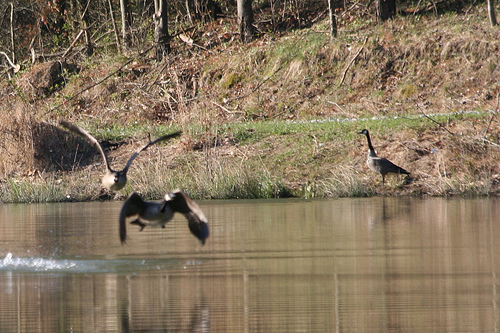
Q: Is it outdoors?
A: Yes, it is outdoors.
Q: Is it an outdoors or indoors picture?
A: It is outdoors.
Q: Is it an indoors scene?
A: No, it is outdoors.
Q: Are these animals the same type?
A: Yes, all the animals are birds.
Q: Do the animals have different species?
A: No, all the animals are birds.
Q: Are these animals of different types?
A: No, all the animals are birds.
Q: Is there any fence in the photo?
A: No, there are no fences.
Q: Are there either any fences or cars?
A: No, there are no fences or cars.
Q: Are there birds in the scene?
A: Yes, there is a bird.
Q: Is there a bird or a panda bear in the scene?
A: Yes, there is a bird.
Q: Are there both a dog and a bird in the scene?
A: No, there is a bird but no dogs.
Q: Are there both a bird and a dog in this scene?
A: No, there is a bird but no dogs.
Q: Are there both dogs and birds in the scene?
A: No, there is a bird but no dogs.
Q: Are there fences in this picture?
A: No, there are no fences.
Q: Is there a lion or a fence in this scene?
A: No, there are no fences or lions.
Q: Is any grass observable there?
A: Yes, there is grass.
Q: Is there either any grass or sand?
A: Yes, there is grass.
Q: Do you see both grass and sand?
A: No, there is grass but no sand.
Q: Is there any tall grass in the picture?
A: Yes, there is tall grass.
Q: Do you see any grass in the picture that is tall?
A: Yes, there is tall grass.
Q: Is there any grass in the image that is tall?
A: Yes, there is grass that is tall.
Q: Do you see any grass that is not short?
A: Yes, there is tall grass.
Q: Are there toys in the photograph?
A: No, there are no toys.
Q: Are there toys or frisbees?
A: No, there are no toys or frisbees.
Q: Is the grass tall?
A: Yes, the grass is tall.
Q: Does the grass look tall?
A: Yes, the grass is tall.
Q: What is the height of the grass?
A: The grass is tall.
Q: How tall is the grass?
A: The grass is tall.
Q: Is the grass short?
A: No, the grass is tall.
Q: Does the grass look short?
A: No, the grass is tall.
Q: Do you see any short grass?
A: No, there is grass but it is tall.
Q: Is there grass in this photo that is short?
A: No, there is grass but it is tall.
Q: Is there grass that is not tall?
A: No, there is grass but it is tall.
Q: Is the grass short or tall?
A: The grass is tall.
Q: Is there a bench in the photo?
A: No, there are no benches.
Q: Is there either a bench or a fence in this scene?
A: No, there are no benches or fences.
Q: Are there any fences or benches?
A: No, there are no benches or fences.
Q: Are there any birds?
A: Yes, there is a bird.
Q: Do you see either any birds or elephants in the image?
A: Yes, there is a bird.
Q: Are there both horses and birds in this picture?
A: No, there is a bird but no horses.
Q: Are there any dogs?
A: No, there are no dogs.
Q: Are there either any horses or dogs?
A: No, there are no dogs or horses.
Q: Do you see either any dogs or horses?
A: No, there are no dogs or horses.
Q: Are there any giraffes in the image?
A: No, there are no giraffes.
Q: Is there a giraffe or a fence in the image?
A: No, there are no giraffes or fences.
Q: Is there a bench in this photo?
A: No, there are no benches.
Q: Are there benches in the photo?
A: No, there are no benches.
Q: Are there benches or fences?
A: No, there are no benches or fences.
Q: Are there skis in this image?
A: No, there are no skis.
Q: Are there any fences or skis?
A: No, there are no skis or fences.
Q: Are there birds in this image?
A: Yes, there is a bird.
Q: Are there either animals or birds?
A: Yes, there is a bird.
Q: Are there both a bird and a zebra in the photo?
A: No, there is a bird but no zebras.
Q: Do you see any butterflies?
A: No, there are no butterflies.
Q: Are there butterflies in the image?
A: No, there are no butterflies.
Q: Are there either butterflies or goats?
A: No, there are no butterflies or goats.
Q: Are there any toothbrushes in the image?
A: No, there are no toothbrushes.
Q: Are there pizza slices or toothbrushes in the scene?
A: No, there are no toothbrushes or pizza slices.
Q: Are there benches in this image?
A: No, there are no benches.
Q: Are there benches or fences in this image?
A: No, there are no benches or fences.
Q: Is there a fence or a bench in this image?
A: No, there are no benches or fences.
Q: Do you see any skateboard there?
A: No, there are no skateboards.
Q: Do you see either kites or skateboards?
A: No, there are no skateboards or kites.